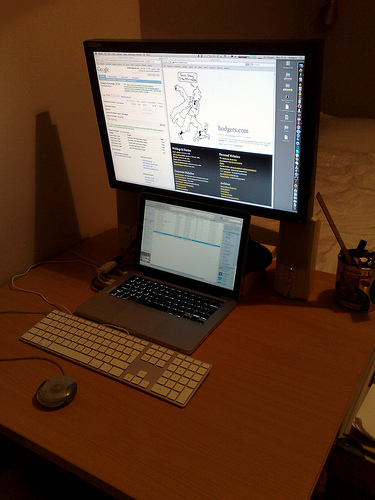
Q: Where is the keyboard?
A: On the desk.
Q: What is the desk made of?
A: Wood.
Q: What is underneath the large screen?
A: A laptop.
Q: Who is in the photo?
A: Nobody.